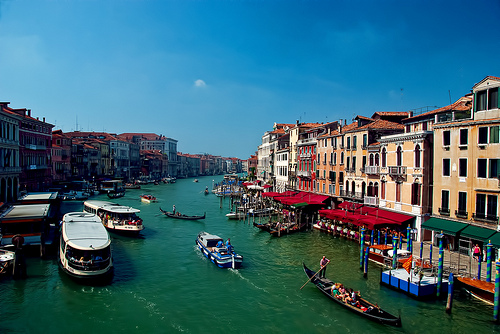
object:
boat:
[380, 267, 442, 299]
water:
[149, 223, 195, 250]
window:
[441, 130, 452, 147]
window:
[457, 126, 470, 147]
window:
[476, 127, 490, 148]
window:
[478, 126, 490, 144]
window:
[440, 159, 452, 178]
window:
[474, 156, 488, 180]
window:
[437, 189, 452, 214]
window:
[472, 88, 488, 110]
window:
[457, 125, 467, 147]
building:
[247, 75, 500, 276]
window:
[485, 87, 500, 109]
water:
[1, 295, 261, 331]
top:
[63, 211, 112, 249]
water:
[160, 184, 196, 209]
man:
[319, 255, 330, 278]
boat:
[192, 232, 245, 270]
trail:
[226, 267, 278, 298]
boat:
[300, 261, 406, 329]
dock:
[381, 216, 500, 300]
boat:
[55, 211, 114, 287]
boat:
[158, 206, 206, 220]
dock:
[251, 190, 329, 232]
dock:
[312, 201, 417, 248]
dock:
[0, 190, 62, 252]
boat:
[81, 199, 144, 234]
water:
[146, 189, 296, 308]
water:
[252, 234, 291, 275]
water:
[143, 221, 194, 304]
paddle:
[300, 261, 331, 289]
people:
[330, 282, 339, 296]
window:
[457, 158, 467, 177]